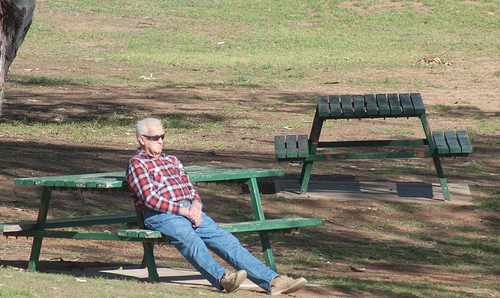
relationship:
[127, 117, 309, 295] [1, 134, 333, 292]
man sitting on bench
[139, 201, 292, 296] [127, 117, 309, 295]
jeans worn by man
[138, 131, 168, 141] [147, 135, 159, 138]
sunglasses protecting eyes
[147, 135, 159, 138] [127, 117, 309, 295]
eyes of man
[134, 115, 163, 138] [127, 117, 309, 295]
hair of man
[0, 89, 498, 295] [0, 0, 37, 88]
shadow from tree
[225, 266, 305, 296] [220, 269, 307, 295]
shoes protecting feet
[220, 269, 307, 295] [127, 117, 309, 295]
feet of man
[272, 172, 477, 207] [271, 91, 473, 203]
concerete slab for table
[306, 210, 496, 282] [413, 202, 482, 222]
ground without grass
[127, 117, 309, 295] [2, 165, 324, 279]
man sitting on bench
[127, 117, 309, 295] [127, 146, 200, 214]
man wearing shirt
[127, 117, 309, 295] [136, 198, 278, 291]
man wearing jeans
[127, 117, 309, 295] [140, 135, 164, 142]
man wearing sunglasses